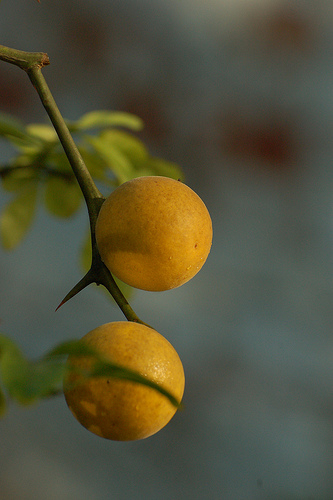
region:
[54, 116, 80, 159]
part of a stalk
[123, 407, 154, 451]
part of a peel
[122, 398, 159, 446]
part of a fruit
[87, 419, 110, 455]
edge of a peel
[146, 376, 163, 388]
part of an orange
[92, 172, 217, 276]
this is an orange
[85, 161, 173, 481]
the oranges are two in number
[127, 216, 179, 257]
the orange is orange in color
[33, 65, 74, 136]
this is the branch of the tree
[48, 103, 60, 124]
the branch is green in color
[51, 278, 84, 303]
this is a thorn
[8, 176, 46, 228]
this is the leaf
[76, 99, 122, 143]
the leaves are green in color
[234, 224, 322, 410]
this is the sky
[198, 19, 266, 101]
the sky is blue in color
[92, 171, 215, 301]
fruit on a tree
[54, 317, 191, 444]
fruit on a tree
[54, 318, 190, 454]
orange on a tree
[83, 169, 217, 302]
orange on a tree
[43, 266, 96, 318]
thorn on a tree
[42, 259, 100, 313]
sharp thorn near oranges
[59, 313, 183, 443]
orange near a thorn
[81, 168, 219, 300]
orange near a thorn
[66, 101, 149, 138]
green leaf on a tree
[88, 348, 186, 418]
green leaf on a tree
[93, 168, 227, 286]
Bright yellow orange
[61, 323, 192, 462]
Bright yellow orange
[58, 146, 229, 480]
Oranges on thorny branch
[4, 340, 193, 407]
Green leave blocking orange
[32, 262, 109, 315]
Thorn on orange bush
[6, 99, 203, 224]
Green leaves on orange bush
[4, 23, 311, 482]
Scene of oranges on orange bush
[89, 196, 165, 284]
Shadow of leave cast on orange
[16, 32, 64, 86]
Broken branch of orange bush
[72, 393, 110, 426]
Small dent in orange on bush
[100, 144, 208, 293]
Orange on the tree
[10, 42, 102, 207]
green branch of orange tree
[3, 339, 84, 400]
blurry orange tree leaves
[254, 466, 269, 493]
dirt on camera screen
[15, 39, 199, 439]
Orange tree branch in photo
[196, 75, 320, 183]
something blurry in the distance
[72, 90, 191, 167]
blurry leaves on the tree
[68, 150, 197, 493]
two oranges on a branch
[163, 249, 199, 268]
water dew on the orange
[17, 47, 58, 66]
branch broken off the tree